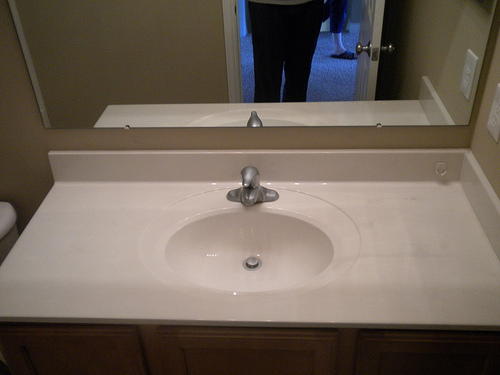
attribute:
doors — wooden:
[50, 316, 430, 367]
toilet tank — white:
[3, 199, 17, 249]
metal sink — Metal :
[177, 232, 317, 287]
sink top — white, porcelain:
[4, 152, 499, 322]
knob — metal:
[378, 32, 397, 58]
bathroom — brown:
[58, 142, 483, 364]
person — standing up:
[325, 2, 363, 58]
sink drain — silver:
[135, 169, 364, 302]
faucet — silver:
[219, 162, 277, 210]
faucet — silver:
[226, 163, 278, 206]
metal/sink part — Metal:
[225, 165, 279, 207]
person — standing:
[237, 0, 346, 87]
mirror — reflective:
[8, 1, 499, 130]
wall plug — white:
[481, 81, 499, 148]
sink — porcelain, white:
[140, 245, 365, 289]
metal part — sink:
[224, 158, 280, 275]